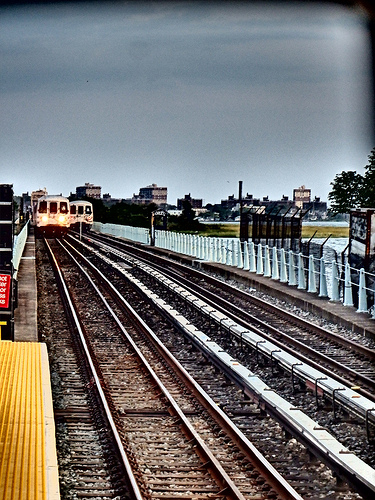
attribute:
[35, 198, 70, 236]
train — one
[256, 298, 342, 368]
tracks — train, set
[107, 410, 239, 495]
tracks — train, set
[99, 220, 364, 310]
fence — white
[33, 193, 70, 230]
train — one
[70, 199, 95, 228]
train — one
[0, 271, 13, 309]
sign — red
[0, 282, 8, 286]
lettering — white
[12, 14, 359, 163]
sky — stormy, gloomy, above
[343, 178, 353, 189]
leaves — green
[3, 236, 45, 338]
workers — railroad 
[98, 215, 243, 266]
rail — white guard 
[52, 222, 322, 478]
track — train 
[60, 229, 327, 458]
tracks —  two train 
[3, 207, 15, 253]
bed —  gravel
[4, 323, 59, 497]
overhang — yellow roofing 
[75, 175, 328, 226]
buildings — taller 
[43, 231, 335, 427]
tracks — two train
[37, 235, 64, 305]
frame — wood 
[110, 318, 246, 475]
tracks — side 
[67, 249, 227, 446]
tracks — side 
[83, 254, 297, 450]
tracks — train , side 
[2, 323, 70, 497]
grate — yellow 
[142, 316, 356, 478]
tracks — train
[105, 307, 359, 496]
tracks — train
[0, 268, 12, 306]
sign — red 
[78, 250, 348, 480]
tracks — train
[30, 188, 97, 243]
trains — electric 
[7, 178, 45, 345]
platform — yellow non slip 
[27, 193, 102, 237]
train — boarding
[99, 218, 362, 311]
railing — white 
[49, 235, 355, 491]
tracks — train 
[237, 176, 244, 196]
chimney — distance, tall 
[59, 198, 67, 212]
visible operator — in the front window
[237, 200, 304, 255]
black fence — tall, chain link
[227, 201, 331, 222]
mixed homes — within trees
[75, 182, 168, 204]
commercial buildings — twin larger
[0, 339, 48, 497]
yellow coloring — on the platform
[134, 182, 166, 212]
building — in the background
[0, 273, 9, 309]
red sign — beside the tracks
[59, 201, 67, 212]
person — on the train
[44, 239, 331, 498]
tracks — on the ground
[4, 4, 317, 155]
blue sky — in the background